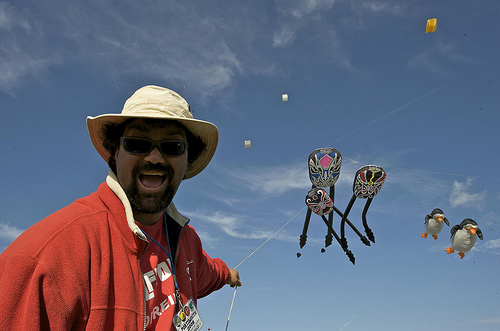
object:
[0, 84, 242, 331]
man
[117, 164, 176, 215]
beard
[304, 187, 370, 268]
kites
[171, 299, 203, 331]
tag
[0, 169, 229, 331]
sweatshirt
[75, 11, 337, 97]
skies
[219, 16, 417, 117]
sky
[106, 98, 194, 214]
head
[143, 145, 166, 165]
nose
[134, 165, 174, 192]
mouth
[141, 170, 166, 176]
teeth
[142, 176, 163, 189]
tongue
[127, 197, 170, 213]
chin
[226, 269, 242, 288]
hand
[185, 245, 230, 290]
arm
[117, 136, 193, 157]
sunglasses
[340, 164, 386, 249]
kite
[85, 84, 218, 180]
hat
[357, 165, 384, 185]
mask